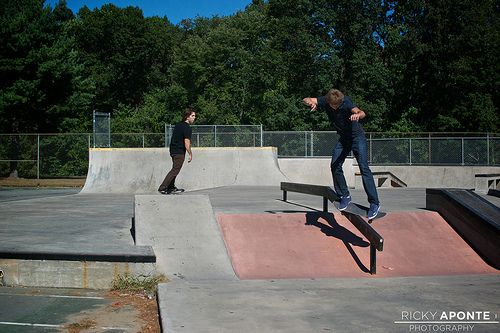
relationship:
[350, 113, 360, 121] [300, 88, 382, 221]
hand of boy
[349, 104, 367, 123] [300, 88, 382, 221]
arm of boy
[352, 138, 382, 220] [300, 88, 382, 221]
leg of boy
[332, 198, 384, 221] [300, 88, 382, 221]
skateboard under boy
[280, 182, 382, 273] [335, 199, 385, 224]
railing under skateboard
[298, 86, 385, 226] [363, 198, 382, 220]
boy wearing shoe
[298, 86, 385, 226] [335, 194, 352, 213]
boy wearing shoe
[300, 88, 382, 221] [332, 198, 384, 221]
boy on skateboard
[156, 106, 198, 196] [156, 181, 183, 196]
boy wearing black shoes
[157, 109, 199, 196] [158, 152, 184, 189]
boy wearing pants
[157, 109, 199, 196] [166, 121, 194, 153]
boy wearing shirt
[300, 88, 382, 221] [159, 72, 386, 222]
boy are skateboarding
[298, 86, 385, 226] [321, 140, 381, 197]
boy wears jeans